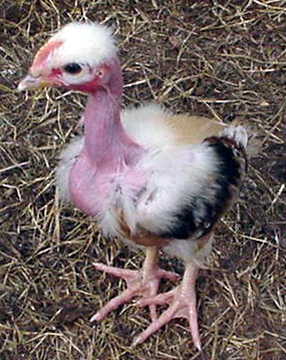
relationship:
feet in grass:
[90, 257, 203, 352] [2, 1, 284, 358]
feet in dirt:
[90, 257, 203, 352] [1, 0, 284, 358]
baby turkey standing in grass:
[14, 21, 254, 350] [2, 1, 284, 358]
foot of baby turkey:
[125, 279, 205, 350] [14, 21, 254, 350]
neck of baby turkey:
[79, 89, 134, 158] [14, 21, 254, 350]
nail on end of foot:
[88, 310, 98, 325] [90, 256, 181, 334]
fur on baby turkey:
[48, 107, 220, 230] [14, 21, 254, 350]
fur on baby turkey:
[161, 130, 244, 245] [14, 21, 254, 350]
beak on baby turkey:
[13, 76, 51, 96] [14, 21, 254, 350]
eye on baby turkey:
[58, 59, 85, 78] [14, 21, 254, 350]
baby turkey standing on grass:
[19, 21, 255, 351] [2, 1, 284, 358]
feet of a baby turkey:
[90, 257, 203, 352] [19, 21, 255, 351]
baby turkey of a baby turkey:
[14, 21, 254, 350] [14, 21, 254, 350]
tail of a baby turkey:
[221, 116, 257, 164] [19, 21, 255, 351]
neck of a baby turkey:
[73, 89, 136, 161] [19, 21, 255, 351]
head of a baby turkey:
[18, 21, 122, 100] [19, 21, 255, 351]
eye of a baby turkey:
[58, 59, 85, 78] [19, 21, 255, 351]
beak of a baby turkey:
[13, 76, 51, 96] [14, 21, 254, 350]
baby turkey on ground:
[14, 21, 254, 350] [211, 251, 269, 324]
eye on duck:
[48, 53, 92, 80] [31, 25, 232, 288]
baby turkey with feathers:
[14, 21, 254, 350] [123, 106, 227, 255]